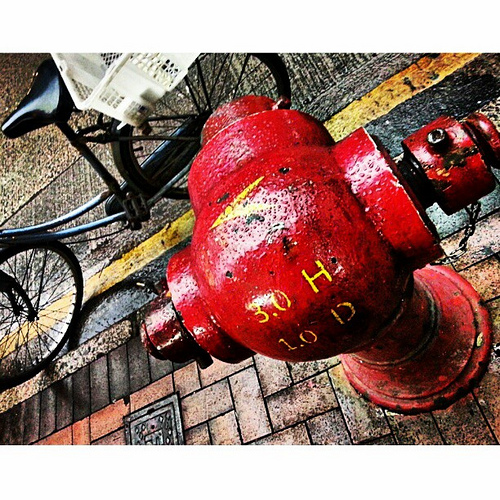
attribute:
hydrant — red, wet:
[120, 119, 495, 409]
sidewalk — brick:
[10, 224, 496, 453]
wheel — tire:
[1, 245, 83, 387]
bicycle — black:
[2, 54, 290, 379]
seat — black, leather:
[5, 62, 71, 136]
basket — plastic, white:
[47, 56, 201, 118]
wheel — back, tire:
[106, 47, 316, 199]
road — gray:
[3, 58, 495, 359]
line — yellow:
[2, 58, 490, 313]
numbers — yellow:
[245, 266, 358, 347]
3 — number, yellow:
[243, 299, 270, 326]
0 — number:
[271, 291, 293, 313]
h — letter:
[300, 260, 333, 292]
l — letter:
[277, 338, 303, 359]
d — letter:
[330, 301, 356, 322]